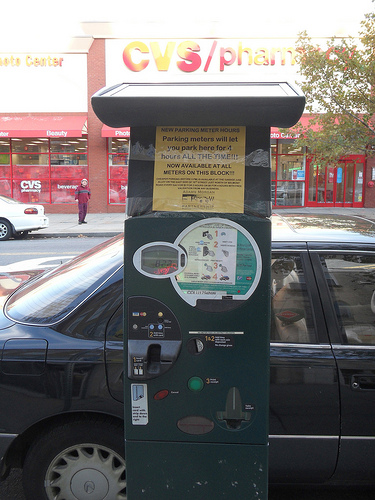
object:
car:
[1, 214, 373, 499]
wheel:
[0, 414, 133, 495]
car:
[0, 193, 47, 240]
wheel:
[0, 218, 13, 241]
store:
[1, 0, 373, 216]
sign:
[121, 39, 353, 83]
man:
[74, 179, 93, 224]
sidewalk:
[29, 205, 374, 237]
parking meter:
[89, 78, 306, 497]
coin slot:
[186, 337, 206, 356]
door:
[307, 241, 375, 498]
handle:
[344, 371, 372, 395]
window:
[323, 251, 374, 347]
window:
[266, 251, 320, 345]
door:
[305, 155, 368, 207]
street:
[0, 236, 116, 275]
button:
[187, 376, 204, 394]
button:
[153, 389, 170, 401]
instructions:
[172, 216, 263, 305]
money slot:
[132, 360, 172, 364]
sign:
[152, 123, 247, 215]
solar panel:
[98, 82, 299, 99]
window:
[0, 138, 11, 169]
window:
[12, 137, 47, 166]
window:
[50, 137, 88, 165]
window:
[108, 137, 131, 166]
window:
[276, 139, 305, 207]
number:
[155, 259, 160, 267]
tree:
[277, 0, 375, 165]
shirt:
[75, 184, 91, 203]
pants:
[78, 204, 87, 221]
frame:
[306, 202, 364, 207]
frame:
[362, 159, 365, 207]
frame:
[305, 154, 308, 208]